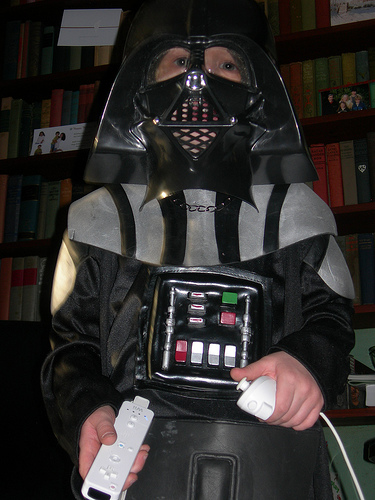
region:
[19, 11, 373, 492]
boy holding game controllers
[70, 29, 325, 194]
boy with green eyes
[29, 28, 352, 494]
boy wearing darth vader costume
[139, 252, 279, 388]
many buttons on costume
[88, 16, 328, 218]
boy smiling under mask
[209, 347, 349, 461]
boy has his fingers on button of controller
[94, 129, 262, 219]
chain link on bottom of mask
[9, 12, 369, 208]
large collection of books behind boy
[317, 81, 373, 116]
picture of a family on bookshelf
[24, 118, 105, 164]
advertisement card on bookshelf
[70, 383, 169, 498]
a white wii contoller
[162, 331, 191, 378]
a small red switch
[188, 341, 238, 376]
three small white switches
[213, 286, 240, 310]
a small green button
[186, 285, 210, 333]
three small gray and red buttuns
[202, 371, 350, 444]
a white wii nunchuck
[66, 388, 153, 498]
hand holding a wii controller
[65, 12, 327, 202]
black darth vader helmet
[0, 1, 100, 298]
books and cards on shelfs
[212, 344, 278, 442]
thumb on a nunchuck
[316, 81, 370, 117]
Family photo on bookshelf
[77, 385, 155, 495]
White Wii remote in boy's hand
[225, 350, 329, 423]
White Wii nunchuk in boy's hand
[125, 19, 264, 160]
Boy's face in Darth Vader mask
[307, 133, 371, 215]
Row of hard backed books on shelf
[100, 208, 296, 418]
Gray and black Darth Vader costume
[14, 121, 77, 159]
White family photo on bookshelf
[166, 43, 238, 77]
Boy's eyes staring through mask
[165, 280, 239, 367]
Red, green and silver buttons on costume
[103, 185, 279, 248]
Black stripes on gray costume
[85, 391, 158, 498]
A wii controller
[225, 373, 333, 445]
A nunchuck wiimote attachment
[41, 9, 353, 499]
A child in a darth vader costume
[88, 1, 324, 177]
A darth vader costume mask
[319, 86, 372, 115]
A family photo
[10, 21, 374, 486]
A large book shelf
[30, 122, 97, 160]
A picture on the book shelf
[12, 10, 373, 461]
A large collection of books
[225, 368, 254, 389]
the joystick on the nunchuck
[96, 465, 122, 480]
The directional pad on the wiimote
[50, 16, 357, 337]
child in darth vader costume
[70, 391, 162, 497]
wii remote game controller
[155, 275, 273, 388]
darth vader life regulation system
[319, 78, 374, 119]
family picture on bookshelf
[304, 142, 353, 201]
2 similar orange books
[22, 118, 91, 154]
postcard with family on bookshelf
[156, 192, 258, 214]
chain across bottom of mask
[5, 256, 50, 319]
gray books with red stripes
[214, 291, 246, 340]
red and green control buttons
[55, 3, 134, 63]
sheet of paper hanging over books